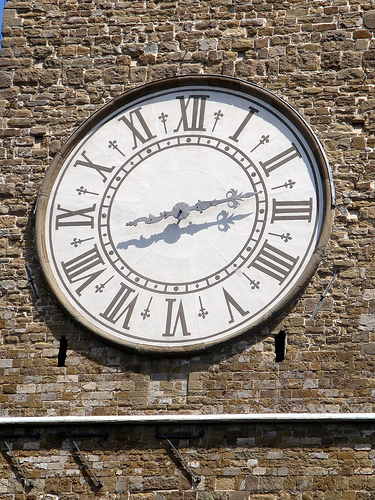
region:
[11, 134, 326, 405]
clock at a cermoinc wall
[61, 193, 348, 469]
clock at a cermoinc wall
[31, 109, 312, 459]
clock at a cermoinc wall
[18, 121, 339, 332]
clock at a cermoinc wall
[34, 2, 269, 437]
clock at a cermoinc wall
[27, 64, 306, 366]
clock at a cermoinc wall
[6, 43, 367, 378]
large clock on stone wall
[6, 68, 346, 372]
clock reads 8:12 approximately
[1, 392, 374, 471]
cement ledge on stone wall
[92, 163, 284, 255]
sun casting shadow on clock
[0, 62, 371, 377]
large clock with Roman Numerals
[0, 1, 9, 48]
blue sky behind clock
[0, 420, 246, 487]
metal brackets on stone wall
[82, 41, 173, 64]
larlge stone protruding from wall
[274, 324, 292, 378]
hole in stone wall under clock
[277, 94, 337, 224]
metal bracket around clock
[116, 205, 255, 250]
shadow from clock hands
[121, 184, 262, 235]
grey clock hand on a clock face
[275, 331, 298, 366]
dark spot on a brick wall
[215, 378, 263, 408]
bricks on a wall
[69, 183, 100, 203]
decoration on a clock face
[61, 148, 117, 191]
roman numeral on a clock face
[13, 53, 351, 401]
clock face on a wall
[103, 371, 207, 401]
tan colored bricks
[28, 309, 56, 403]
wall of a brick building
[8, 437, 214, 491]
area under a shelf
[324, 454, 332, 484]
There are is some green on the brick here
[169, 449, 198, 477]
There is a steel railing visible here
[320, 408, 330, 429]
There is a white ledge here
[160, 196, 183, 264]
There is a black hand visible here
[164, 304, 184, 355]
There are Roman numerals visible here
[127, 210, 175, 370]
Jackson Mingus took this photo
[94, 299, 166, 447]
This photo has a great deal of detail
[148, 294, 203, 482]
This photo is really quite lovely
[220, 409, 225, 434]
part of a board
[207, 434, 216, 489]
part of a stone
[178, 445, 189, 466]
part of a brick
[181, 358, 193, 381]
part of a clock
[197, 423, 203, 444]
part of a shelf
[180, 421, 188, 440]
edge of a shelf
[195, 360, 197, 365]
part of a clock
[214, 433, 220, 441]
part of a building